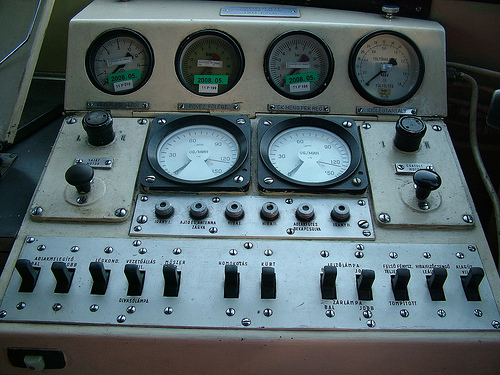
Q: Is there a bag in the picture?
A: No, there are no bags.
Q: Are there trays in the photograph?
A: No, there are no trays.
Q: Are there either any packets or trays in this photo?
A: No, there are no trays or packets.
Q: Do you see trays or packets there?
A: No, there are no trays or packets.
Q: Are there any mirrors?
A: No, there are no mirrors.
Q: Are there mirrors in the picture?
A: No, there are no mirrors.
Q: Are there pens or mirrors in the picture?
A: No, there are no mirrors or pens.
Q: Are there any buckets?
A: No, there are no buckets.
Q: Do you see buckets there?
A: No, there are no buckets.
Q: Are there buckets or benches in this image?
A: No, there are no buckets or benches.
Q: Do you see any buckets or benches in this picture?
A: No, there are no buckets or benches.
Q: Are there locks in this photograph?
A: No, there are no locks.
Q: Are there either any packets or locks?
A: No, there are no locks or packets.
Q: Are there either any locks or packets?
A: No, there are no locks or packets.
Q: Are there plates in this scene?
A: Yes, there is a plate.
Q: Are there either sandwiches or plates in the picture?
A: Yes, there is a plate.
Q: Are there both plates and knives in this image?
A: No, there is a plate but no knives.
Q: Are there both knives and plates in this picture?
A: No, there is a plate but no knives.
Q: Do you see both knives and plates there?
A: No, there is a plate but no knives.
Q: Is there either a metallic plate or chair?
A: Yes, there is a metal plate.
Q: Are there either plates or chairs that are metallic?
A: Yes, the plate is metallic.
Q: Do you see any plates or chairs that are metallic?
A: Yes, the plate is metallic.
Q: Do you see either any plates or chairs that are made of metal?
A: Yes, the plate is made of metal.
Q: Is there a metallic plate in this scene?
A: Yes, there is a metal plate.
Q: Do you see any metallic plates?
A: Yes, there is a metal plate.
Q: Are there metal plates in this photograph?
A: Yes, there is a metal plate.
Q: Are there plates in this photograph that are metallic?
A: Yes, there is a plate that is metallic.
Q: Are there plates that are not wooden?
A: Yes, there is a metallic plate.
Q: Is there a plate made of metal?
A: Yes, there is a plate that is made of metal.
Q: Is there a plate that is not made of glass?
A: Yes, there is a plate that is made of metal.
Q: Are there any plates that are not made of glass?
A: Yes, there is a plate that is made of metal.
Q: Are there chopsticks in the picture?
A: No, there are no chopsticks.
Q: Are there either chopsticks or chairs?
A: No, there are no chopsticks or chairs.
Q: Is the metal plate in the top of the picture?
A: Yes, the plate is in the top of the image.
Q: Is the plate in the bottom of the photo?
A: No, the plate is in the top of the image.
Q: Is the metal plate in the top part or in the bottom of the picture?
A: The plate is in the top of the image.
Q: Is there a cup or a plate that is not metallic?
A: No, there is a plate but it is metallic.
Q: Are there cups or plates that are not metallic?
A: No, there is a plate but it is metallic.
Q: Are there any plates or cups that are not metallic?
A: No, there is a plate but it is metallic.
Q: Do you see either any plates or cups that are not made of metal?
A: No, there is a plate but it is made of metal.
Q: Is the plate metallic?
A: Yes, the plate is metallic.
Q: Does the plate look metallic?
A: Yes, the plate is metallic.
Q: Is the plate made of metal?
A: Yes, the plate is made of metal.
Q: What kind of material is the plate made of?
A: The plate is made of metal.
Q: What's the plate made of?
A: The plate is made of metal.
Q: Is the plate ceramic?
A: No, the plate is metallic.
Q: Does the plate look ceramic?
A: No, the plate is metallic.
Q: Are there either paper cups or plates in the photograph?
A: No, there is a plate but it is metallic.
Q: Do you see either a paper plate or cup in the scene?
A: No, there is a plate but it is metallic.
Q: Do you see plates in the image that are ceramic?
A: No, there is a plate but it is metallic.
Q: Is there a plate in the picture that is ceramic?
A: No, there is a plate but it is metallic.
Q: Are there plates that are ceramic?
A: No, there is a plate but it is metallic.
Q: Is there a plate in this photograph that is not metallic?
A: No, there is a plate but it is metallic.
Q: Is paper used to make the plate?
A: No, the plate is made of metal.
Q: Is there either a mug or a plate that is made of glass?
A: No, there is a plate but it is made of metal.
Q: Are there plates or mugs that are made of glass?
A: No, there is a plate but it is made of metal.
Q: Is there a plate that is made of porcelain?
A: No, there is a plate but it is made of metal.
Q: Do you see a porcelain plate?
A: No, there is a plate but it is made of metal.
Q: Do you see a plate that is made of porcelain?
A: No, there is a plate but it is made of metal.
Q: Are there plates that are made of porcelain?
A: No, there is a plate but it is made of metal.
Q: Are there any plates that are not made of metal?
A: No, there is a plate but it is made of metal.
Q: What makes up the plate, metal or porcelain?
A: The plate is made of metal.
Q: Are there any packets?
A: No, there are no packets.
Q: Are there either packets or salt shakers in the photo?
A: No, there are no packets or salt shakers.